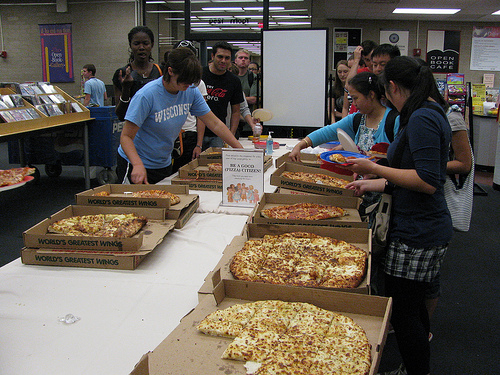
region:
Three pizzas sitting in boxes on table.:
[134, 186, 398, 372]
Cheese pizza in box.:
[202, 293, 367, 373]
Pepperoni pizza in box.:
[259, 197, 356, 222]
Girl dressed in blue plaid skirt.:
[376, 236, 453, 303]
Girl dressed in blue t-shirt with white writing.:
[114, 81, 221, 163]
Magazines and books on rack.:
[3, 77, 99, 187]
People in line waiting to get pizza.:
[103, 21, 266, 123]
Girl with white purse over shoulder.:
[445, 101, 498, 238]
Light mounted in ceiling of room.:
[390, 0, 462, 20]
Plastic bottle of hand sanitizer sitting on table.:
[263, 125, 281, 156]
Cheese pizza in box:
[196, 299, 386, 374]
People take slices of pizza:
[151, 20, 497, 275]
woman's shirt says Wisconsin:
[113, 38, 244, 178]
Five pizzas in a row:
[264, 125, 371, 369]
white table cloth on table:
[21, 277, 116, 364]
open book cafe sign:
[424, 44, 463, 76]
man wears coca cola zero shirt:
[200, 30, 244, 140]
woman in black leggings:
[381, 43, 453, 373]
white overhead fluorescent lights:
[161, 4, 483, 44]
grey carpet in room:
[443, 245, 482, 367]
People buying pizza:
[311, 38, 486, 303]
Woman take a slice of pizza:
[281, 69, 398, 171]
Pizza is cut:
[177, 284, 394, 371]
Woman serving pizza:
[108, 36, 259, 189]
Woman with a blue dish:
[313, 49, 468, 374]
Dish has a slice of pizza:
[318, 140, 373, 174]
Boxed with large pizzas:
[21, 166, 203, 268]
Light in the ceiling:
[383, 4, 466, 24]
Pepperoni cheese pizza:
[252, 189, 362, 226]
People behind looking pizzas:
[208, 40, 276, 120]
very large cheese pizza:
[195, 301, 368, 374]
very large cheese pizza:
[230, 232, 366, 289]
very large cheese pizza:
[52, 212, 142, 239]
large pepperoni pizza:
[262, 200, 344, 219]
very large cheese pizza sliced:
[95, 185, 176, 201]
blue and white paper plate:
[316, 145, 362, 165]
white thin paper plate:
[335, 127, 356, 150]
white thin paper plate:
[251, 106, 273, 121]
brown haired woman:
[340, 55, 451, 367]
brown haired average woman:
[115, 45, 245, 181]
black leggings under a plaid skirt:
[383, 240, 444, 373]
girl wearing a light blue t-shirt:
[116, 45, 241, 185]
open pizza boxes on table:
[4, 211, 344, 373]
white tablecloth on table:
[0, 207, 265, 372]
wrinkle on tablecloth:
[171, 212, 214, 257]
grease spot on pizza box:
[216, 359, 231, 374]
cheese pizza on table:
[198, 300, 371, 374]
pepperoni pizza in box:
[260, 200, 350, 221]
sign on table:
[219, 148, 264, 212]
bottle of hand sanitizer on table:
[264, 130, 279, 154]